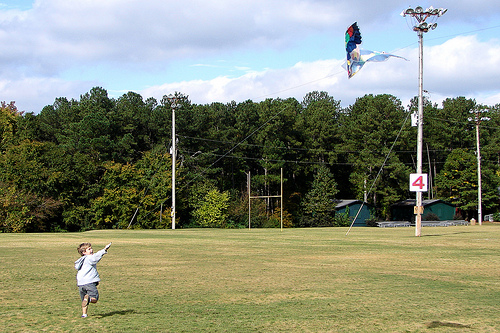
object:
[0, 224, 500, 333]
grass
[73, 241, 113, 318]
boy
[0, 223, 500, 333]
field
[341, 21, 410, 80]
kite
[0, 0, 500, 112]
sky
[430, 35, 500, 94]
clouds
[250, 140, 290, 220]
trees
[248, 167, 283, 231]
goal post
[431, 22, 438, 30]
lights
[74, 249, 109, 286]
hoodie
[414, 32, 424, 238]
pole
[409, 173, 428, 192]
sign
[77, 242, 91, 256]
hair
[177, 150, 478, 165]
wires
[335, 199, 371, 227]
building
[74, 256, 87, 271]
hood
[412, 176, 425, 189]
number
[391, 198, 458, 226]
house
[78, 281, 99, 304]
shorts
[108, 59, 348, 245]
string